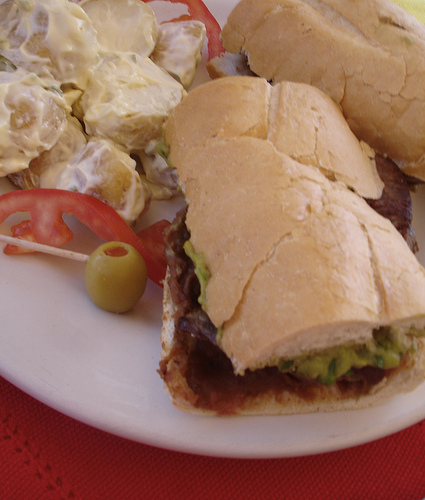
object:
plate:
[0, 0, 424, 461]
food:
[204, 0, 425, 184]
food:
[155, 74, 425, 420]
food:
[82, 238, 148, 315]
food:
[0, 184, 172, 286]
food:
[145, 18, 208, 91]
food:
[0, 63, 73, 181]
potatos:
[58, 130, 151, 233]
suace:
[45, 0, 96, 84]